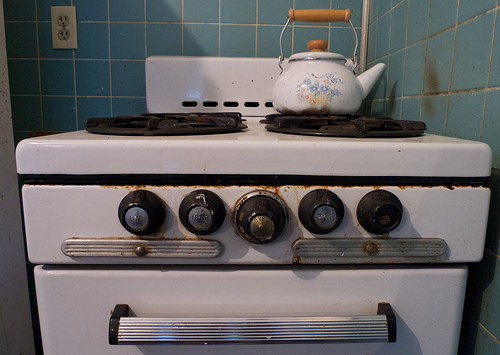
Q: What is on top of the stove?
A: Teapot.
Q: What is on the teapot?
A: Flowers.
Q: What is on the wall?
A: Tiles.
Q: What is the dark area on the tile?
A: Burn mark.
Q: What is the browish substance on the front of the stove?
A: Rust.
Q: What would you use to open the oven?
A: The handle.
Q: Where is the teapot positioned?
A: Back right burner.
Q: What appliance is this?
A: Stove an oven.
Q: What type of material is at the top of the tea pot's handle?
A: Wood.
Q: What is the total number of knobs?
A: Five.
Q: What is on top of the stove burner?
A: Teapot.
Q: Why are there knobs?
A: To adjust the heat of the stove.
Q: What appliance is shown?
A: Stove.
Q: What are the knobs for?
A: To control the heat.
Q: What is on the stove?
A: Kettle.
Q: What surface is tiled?
A: Walls.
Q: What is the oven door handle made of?
A: Metal.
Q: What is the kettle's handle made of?
A: Wood.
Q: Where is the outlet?
A: On the wall.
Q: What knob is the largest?
A: The middle one.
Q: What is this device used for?
A: To cook.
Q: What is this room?
A: Kitchen.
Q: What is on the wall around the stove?
A: Blue tiles.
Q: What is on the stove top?
A: A tea kettle.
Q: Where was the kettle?
A: On the stove.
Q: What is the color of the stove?
A: White.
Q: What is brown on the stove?
A: Rust.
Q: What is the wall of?
A: Tiles.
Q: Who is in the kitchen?
A: No one.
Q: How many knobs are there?
A: 5.